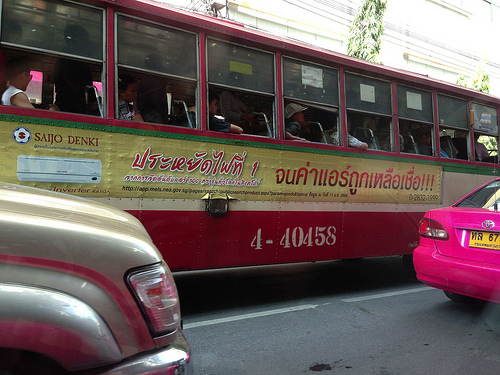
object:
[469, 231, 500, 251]
license plate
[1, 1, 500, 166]
row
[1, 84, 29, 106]
shirt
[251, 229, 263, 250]
number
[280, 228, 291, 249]
number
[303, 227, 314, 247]
number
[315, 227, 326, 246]
number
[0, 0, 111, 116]
window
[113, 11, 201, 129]
window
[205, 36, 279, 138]
window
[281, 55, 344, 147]
window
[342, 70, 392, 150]
window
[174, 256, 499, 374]
road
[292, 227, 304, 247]
number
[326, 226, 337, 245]
number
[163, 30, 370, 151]
window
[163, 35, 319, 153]
window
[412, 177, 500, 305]
car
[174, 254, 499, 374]
street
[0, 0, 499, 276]
red bus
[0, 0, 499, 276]
traffic vehicles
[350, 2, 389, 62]
tree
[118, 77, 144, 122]
asian people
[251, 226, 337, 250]
4-40458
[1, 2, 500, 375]
picture taken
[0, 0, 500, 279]
bus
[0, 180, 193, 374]
another car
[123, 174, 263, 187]
stripe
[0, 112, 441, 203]
an ad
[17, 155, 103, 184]
logo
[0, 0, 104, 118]
open windows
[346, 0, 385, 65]
plant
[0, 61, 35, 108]
person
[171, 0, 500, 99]
building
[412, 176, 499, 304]
toyota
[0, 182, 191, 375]
car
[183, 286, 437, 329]
white line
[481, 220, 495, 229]
emblem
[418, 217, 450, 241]
light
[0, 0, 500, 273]
city bus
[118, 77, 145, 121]
person sitting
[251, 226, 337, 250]
bus numbers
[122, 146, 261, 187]
asian characters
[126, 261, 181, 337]
front headlight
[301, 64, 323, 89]
white paper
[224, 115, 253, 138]
arm on edge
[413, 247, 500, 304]
pink bumper